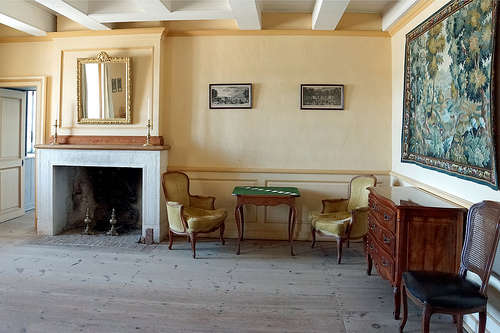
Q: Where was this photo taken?
A: In a living room.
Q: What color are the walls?
A: Yellow.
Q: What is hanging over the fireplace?
A: A mirror.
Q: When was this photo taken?
A: In the daytime.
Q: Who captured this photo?
A: A photographer.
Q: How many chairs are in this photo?
A: Three.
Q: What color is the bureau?
A: Brown.